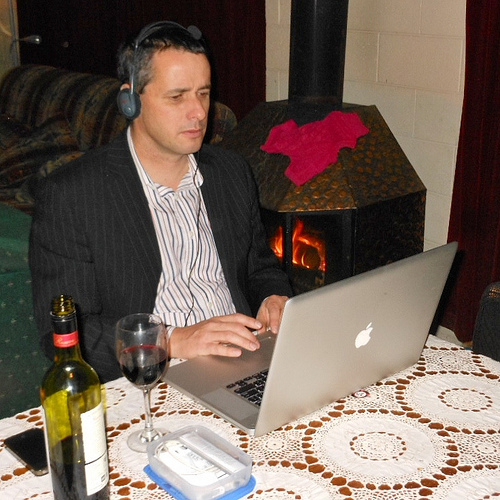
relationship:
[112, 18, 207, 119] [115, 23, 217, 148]
headphone on head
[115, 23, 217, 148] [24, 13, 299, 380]
head of man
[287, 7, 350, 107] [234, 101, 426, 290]
pipe to a fireplace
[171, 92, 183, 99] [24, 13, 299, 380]
eye of man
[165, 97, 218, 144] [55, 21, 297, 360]
nose of man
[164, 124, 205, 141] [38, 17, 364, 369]
mouth of man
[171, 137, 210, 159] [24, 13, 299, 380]
chin of man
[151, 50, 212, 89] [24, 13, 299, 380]
forehead of man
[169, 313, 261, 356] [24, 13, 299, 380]
hand of man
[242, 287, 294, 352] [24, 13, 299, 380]
hand of man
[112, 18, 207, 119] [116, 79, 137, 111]
headphone on ear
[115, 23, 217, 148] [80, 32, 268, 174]
head of man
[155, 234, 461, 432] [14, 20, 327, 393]
laptop in front of man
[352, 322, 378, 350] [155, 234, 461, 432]
apple logo on laptop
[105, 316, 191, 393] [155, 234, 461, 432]
glass next to laptop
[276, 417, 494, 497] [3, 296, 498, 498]
tablecloth on table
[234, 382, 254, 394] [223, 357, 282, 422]
key on keyboard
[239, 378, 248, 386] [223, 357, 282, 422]
key on keyboard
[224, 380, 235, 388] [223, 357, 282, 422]
key on keyboard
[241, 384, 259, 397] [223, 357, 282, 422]
key on keyboard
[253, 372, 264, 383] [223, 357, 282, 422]
key on keyboard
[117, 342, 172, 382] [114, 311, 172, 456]
liquid in glass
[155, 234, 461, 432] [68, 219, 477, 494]
laptop on table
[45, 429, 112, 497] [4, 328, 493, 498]
wine on table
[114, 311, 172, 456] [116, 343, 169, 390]
glass of wine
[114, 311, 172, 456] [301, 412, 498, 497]
glass on table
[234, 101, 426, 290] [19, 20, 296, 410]
fireplace behind man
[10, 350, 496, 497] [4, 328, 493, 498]
table cloth on table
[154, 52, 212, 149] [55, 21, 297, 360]
face of man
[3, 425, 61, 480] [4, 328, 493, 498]
phone on table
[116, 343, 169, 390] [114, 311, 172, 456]
wine in glass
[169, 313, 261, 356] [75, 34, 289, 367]
hand of man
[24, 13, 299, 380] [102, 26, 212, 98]
man has hair